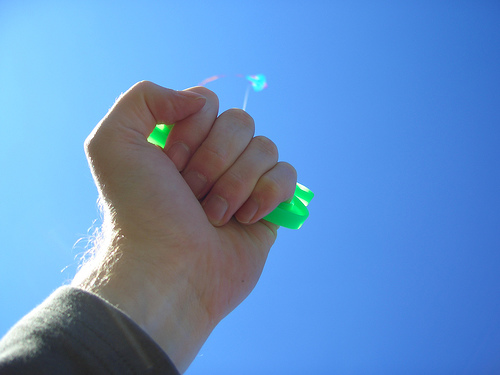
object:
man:
[1, 78, 306, 372]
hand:
[81, 78, 298, 308]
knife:
[144, 117, 315, 235]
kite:
[244, 71, 267, 93]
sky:
[0, 0, 499, 373]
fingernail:
[203, 193, 227, 223]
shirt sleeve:
[0, 274, 179, 374]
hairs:
[82, 250, 94, 262]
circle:
[145, 120, 175, 153]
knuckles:
[126, 78, 165, 93]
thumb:
[94, 78, 206, 144]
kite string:
[243, 90, 250, 111]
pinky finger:
[235, 159, 297, 225]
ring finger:
[205, 135, 280, 231]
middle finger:
[182, 107, 256, 200]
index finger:
[163, 85, 220, 170]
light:
[2, 2, 75, 59]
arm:
[1, 254, 202, 373]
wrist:
[97, 230, 214, 336]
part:
[258, 81, 267, 89]